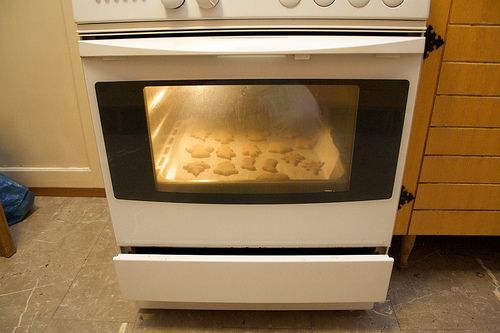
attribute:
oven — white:
[94, 72, 410, 210]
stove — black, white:
[61, 1, 441, 304]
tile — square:
[32, 193, 112, 330]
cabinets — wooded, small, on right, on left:
[393, 6, 497, 243]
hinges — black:
[399, 23, 467, 216]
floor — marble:
[31, 192, 114, 322]